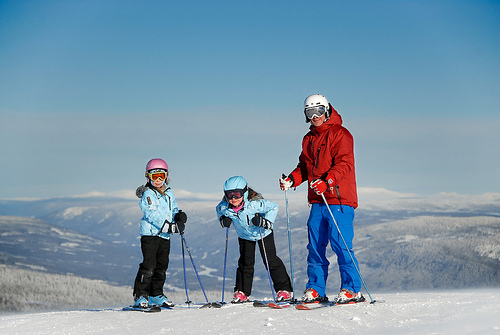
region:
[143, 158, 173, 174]
a pink helmet on a girl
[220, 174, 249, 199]
a blue helmet on a girl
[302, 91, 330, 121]
a white helmet on a man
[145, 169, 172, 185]
yellow framed goggles on a little girl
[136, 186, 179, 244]
a light blue coat on a little girl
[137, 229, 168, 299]
black pants on a little girl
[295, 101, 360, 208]
a red coat on a man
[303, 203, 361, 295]
blue pants on a man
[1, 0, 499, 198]
a blue sky behind three people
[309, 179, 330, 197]
a red and white glove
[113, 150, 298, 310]
Two girls skiing.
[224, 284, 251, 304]
Pink boots on skis.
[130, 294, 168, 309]
Blue shoes on skis.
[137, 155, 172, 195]
Pink helmet on the head.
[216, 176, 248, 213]
blue helmet on the head.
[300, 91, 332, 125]
White helmet on the heads.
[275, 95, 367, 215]
Red jacket on the person.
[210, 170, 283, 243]
Blue jacket on the girl.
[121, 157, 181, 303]
Black snow pants on the girl.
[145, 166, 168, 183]
Goggles on the girl.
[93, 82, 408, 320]
an adult with two children skiing high on a mountain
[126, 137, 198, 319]
young girl with a pink helmet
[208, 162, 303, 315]
young girl bending forward on skis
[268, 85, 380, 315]
adult in skis and a red jacket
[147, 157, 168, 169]
pink helmet the girl is wearing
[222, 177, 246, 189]
blue helmet the girl is wearing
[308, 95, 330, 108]
white helmet the adult is wearing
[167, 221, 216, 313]
blue ski poles the girl is using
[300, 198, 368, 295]
blue ski pants the adult is wearing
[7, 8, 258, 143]
very blue and clear ski above the mountains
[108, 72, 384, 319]
the family on the snowy mountain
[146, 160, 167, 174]
the pink helmet on the girl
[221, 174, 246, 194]
the childs blue helmet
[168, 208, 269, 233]
the black gloves on the girls hands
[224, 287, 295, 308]
the pink boots in the skies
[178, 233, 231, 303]
the blue ski poles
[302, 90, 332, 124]
the white helmet on the man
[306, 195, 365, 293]
the blue pants on the man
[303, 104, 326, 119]
the black goggles on the mans face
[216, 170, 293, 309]
the girl leaning over on her skies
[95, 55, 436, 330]
they are on skis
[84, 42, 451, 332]
a family that is skiing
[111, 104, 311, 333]
they have the same jacket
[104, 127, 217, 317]
she is wearing a pink helmet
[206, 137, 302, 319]
her helmet is blue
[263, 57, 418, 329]
his jacket is red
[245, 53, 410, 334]
his pants are blue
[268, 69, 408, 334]
his helmet is white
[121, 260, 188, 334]
her boots are blue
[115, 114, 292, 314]
they both have black pants